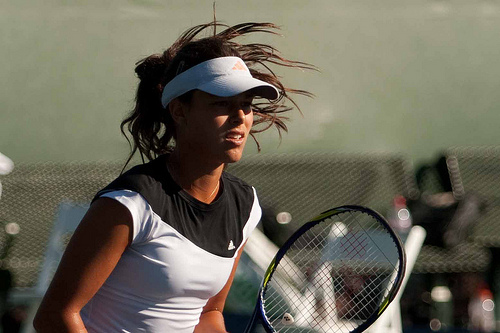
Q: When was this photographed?
A: Daytime.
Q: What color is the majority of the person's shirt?
A: White.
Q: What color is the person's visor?
A: White.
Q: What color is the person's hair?
A: Brown.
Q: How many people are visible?
A: One.